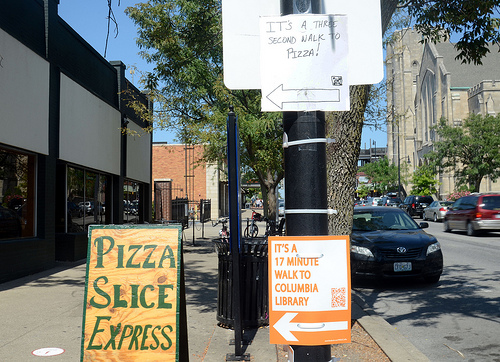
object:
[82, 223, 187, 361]
board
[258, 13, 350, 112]
paper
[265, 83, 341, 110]
arrow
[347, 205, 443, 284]
car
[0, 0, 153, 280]
building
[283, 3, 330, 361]
pole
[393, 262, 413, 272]
plate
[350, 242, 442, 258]
lights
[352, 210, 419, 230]
glass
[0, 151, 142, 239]
windows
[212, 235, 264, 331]
trash bin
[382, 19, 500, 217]
church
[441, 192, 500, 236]
van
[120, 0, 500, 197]
tree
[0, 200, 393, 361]
sidewalk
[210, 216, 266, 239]
bicycles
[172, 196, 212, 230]
fence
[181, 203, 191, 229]
person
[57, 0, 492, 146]
sky